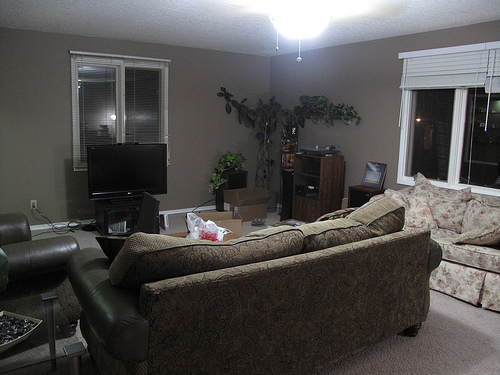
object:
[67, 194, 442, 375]
sofa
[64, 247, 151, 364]
arm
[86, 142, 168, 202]
tv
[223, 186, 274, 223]
box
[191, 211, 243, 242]
box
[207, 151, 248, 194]
plant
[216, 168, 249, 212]
speaker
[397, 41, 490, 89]
blind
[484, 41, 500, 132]
blind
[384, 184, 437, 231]
pillow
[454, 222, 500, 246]
pillow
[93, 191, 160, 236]
entertainment center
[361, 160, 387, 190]
picture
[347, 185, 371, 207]
speaker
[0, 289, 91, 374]
table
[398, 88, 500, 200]
window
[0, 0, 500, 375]
living room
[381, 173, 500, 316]
sofa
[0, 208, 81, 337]
chair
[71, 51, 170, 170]
window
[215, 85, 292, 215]
plant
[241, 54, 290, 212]
corner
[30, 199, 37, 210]
outlet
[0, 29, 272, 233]
wall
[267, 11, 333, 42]
light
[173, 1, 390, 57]
ceiling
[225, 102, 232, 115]
leaf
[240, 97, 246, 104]
leaf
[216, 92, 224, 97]
leaf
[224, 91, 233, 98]
leaf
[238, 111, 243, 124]
leaf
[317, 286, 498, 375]
floor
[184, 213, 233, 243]
bag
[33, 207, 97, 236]
cord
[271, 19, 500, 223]
wall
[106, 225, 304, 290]
cushion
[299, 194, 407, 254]
cushion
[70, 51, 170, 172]
frame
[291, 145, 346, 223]
stand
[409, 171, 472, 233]
cushion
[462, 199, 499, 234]
cushion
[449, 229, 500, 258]
cushion